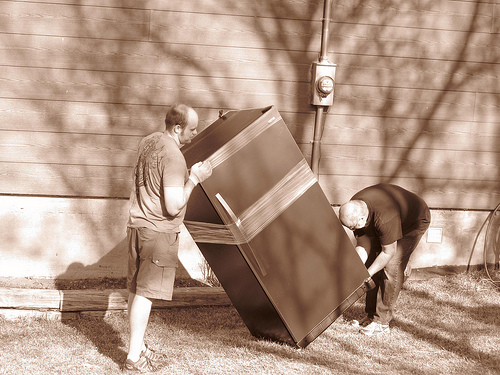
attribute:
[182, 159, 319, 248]
tape — white